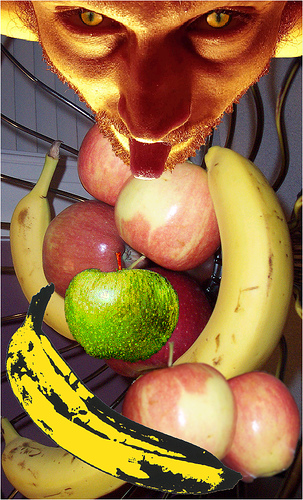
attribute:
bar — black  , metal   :
[0, 98, 83, 167]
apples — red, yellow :
[122, 340, 301, 479]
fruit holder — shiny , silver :
[3, 32, 301, 490]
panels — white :
[2, 37, 96, 157]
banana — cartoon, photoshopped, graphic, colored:
[14, 293, 243, 489]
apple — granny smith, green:
[70, 275, 169, 346]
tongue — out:
[130, 127, 175, 182]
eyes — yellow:
[69, 10, 251, 30]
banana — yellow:
[202, 136, 288, 387]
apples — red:
[53, 158, 217, 274]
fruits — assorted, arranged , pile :
[12, 143, 283, 479]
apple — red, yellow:
[122, 164, 223, 267]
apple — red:
[45, 204, 116, 276]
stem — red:
[104, 245, 133, 276]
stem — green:
[159, 334, 188, 375]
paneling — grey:
[8, 49, 92, 154]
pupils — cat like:
[213, 10, 223, 28]